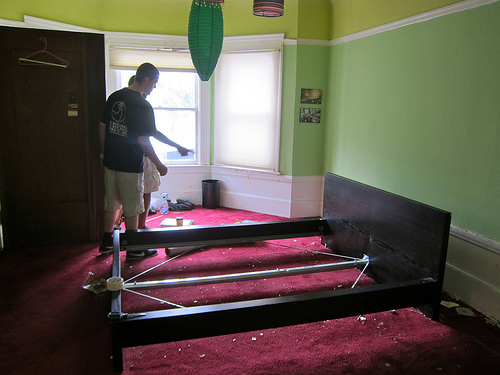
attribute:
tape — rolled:
[106, 270, 123, 290]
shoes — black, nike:
[93, 236, 158, 262]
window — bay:
[108, 31, 284, 178]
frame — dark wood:
[105, 212, 427, 371]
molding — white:
[252, 19, 483, 68]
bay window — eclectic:
[131, 59, 213, 167]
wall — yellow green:
[311, 20, 477, 184]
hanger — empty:
[15, 34, 70, 69]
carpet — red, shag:
[136, 161, 431, 346]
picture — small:
[300, 87, 322, 103]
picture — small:
[298, 107, 323, 123]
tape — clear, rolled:
[103, 268, 125, 290]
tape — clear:
[105, 276, 124, 292]